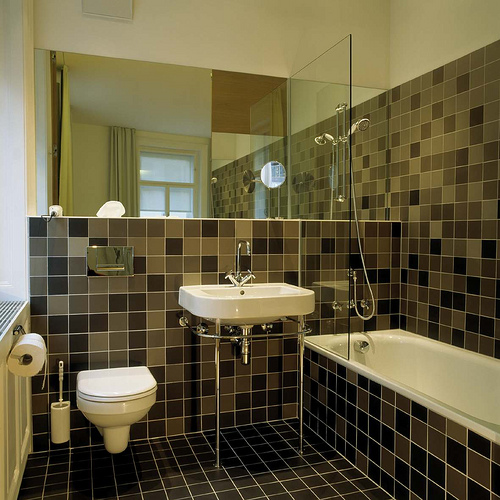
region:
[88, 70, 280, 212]
a mirror on the wall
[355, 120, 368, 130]
a shower head in the bathroom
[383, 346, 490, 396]
a water bath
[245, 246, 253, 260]
a tap in the bathroom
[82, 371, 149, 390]
a white toilet lid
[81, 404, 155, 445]
a white toilet bowl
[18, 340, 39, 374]
a white tissue paper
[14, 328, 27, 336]
a tissue holder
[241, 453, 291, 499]
black tiles on the floor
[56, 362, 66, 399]
the handle of a toilet brush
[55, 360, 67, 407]
A white toilet brush handle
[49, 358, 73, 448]
A white toilet brush in a white holder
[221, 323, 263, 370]
Silver plumbing pipes under the sink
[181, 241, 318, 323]
A white bathroom sink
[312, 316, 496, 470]
A white bathtub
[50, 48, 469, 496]
Tiles on the walls and floors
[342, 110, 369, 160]
A silver shower head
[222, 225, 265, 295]
Silver sink fixtures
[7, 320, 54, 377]
A white roll of toilet paper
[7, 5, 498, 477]
a bathroom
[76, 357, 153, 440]
the toilet in the bathroom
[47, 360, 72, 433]
a toilet brush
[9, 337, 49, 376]
a roll of toilet paper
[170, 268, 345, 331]
the sink in the bathroom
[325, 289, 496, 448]
a bath tub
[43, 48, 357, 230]
a mirror on the wall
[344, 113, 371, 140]
the head of the shower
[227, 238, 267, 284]
the faucet on the sine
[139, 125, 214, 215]
a window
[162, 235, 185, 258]
The ceramic tile is brown.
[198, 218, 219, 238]
The ceramic tile is brown.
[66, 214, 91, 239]
The ceramic tile is brown.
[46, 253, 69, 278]
The ceramic tile is brown.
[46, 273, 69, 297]
The ceramic tile is brown.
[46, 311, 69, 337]
The ceramic tile is brown.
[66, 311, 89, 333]
The ceramic tile is brown.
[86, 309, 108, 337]
The ceramic tile is brown.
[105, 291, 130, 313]
The ceramic tile is brown.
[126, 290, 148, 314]
The ceramic tile is brown.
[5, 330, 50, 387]
Role of toilet paper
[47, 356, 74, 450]
White toilet bowl cleaner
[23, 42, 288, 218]
Square front facing mirror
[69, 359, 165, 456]
Toilet that is closed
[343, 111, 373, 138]
Small round shower head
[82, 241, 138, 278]
Small place to hold soap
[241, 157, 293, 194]
Small round side mirror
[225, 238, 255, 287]
Silver faucet with knobs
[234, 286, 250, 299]
Small hole inside of sink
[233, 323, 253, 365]
Short pipe directly under the sink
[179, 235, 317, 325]
stainless steel faucet on white sink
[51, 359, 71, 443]
toilet brush in toilet brush container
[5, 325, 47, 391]
toilet paper on hanger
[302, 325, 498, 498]
brown tile around bathtub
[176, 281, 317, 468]
white sink on stainless steel legs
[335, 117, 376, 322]
handheld showerhead on metal tube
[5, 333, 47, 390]
toilet paper is white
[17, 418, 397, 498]
floor is brown tile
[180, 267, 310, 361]
white sink attached directly on wall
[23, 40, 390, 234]
large mirror covers all wall width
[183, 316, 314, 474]
sink has chrome metal support